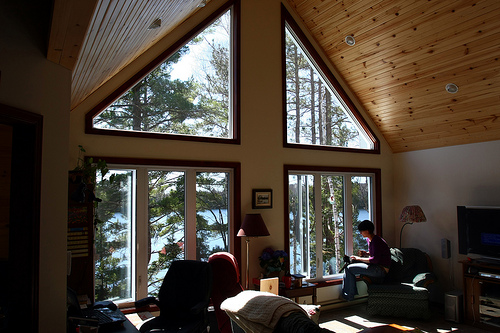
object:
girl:
[338, 219, 393, 303]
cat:
[337, 254, 370, 274]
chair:
[364, 271, 434, 322]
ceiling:
[282, 0, 499, 156]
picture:
[251, 188, 273, 211]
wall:
[0, 0, 397, 333]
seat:
[132, 258, 216, 333]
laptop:
[65, 288, 126, 332]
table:
[87, 298, 138, 333]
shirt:
[365, 234, 392, 269]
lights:
[443, 81, 459, 94]